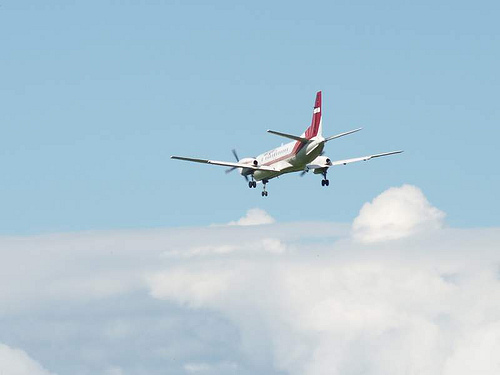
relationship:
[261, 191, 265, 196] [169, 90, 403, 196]
wheel on airplane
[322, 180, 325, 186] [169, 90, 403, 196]
wheel on airplane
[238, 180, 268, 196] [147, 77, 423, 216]
wheel on airplane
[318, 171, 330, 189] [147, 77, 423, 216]
wheel on airplane